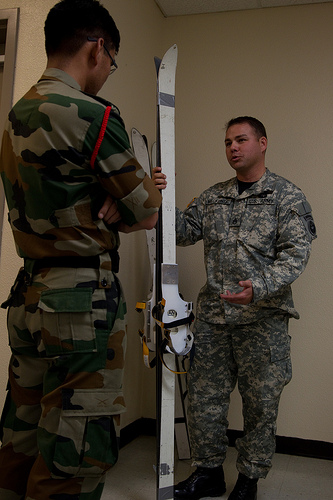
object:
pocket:
[51, 389, 127, 478]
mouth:
[230, 155, 241, 161]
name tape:
[206, 197, 231, 204]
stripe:
[154, 483, 180, 499]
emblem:
[301, 213, 317, 239]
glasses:
[86, 36, 118, 75]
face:
[88, 44, 115, 96]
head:
[45, 0, 122, 99]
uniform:
[175, 165, 319, 481]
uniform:
[0, 64, 165, 498]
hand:
[151, 166, 176, 189]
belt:
[21, 253, 121, 273]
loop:
[99, 253, 112, 289]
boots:
[173, 466, 227, 499]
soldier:
[149, 116, 318, 500]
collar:
[220, 169, 276, 199]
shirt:
[164, 168, 317, 329]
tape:
[159, 91, 177, 108]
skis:
[136, 44, 198, 499]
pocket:
[38, 286, 99, 356]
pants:
[0, 270, 128, 499]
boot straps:
[151, 300, 196, 376]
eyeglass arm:
[87, 36, 117, 67]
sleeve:
[249, 191, 318, 304]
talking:
[226, 151, 244, 163]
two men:
[0, 0, 319, 499]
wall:
[147, 10, 315, 427]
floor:
[96, 429, 329, 497]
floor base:
[122, 418, 328, 459]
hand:
[219, 279, 253, 305]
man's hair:
[222, 116, 267, 141]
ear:
[91, 36, 104, 66]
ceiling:
[154, 0, 324, 15]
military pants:
[186, 315, 292, 479]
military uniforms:
[175, 168, 320, 500]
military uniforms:
[0, 69, 164, 499]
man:
[151, 116, 319, 498]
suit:
[177, 167, 317, 478]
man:
[0, 0, 163, 499]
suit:
[0, 70, 164, 499]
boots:
[226, 473, 258, 499]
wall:
[2, 2, 162, 448]